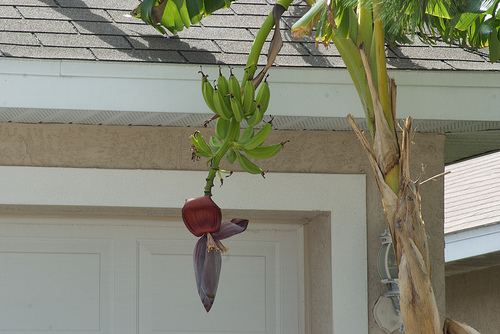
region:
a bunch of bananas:
[189, 71, 291, 171]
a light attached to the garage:
[372, 207, 434, 317]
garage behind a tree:
[0, 1, 499, 331]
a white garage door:
[0, 210, 305, 331]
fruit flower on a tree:
[179, 194, 249, 311]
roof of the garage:
[0, 0, 497, 70]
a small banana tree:
[139, 0, 498, 331]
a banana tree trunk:
[325, 19, 445, 330]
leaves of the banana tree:
[139, 3, 499, 60]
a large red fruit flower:
[180, 197, 250, 315]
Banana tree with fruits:
[135, 0, 499, 330]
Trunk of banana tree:
[344, 53, 473, 332]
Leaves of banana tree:
[132, 2, 499, 58]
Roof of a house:
[5, 0, 498, 69]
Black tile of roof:
[35, 29, 133, 49]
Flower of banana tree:
[176, 190, 250, 314]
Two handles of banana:
[176, 61, 287, 176]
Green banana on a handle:
[231, 150, 267, 181]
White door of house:
[5, 210, 303, 330]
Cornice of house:
[3, 61, 499, 127]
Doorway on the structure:
[5, 148, 385, 331]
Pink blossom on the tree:
[171, 192, 248, 311]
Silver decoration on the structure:
[371, 226, 411, 319]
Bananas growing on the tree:
[192, 61, 285, 175]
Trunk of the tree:
[353, 118, 444, 330]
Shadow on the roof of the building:
[46, 3, 220, 62]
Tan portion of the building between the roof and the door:
[5, 126, 172, 161]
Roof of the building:
[5, 3, 52, 51]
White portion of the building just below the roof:
[8, 66, 188, 103]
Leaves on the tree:
[339, 8, 492, 50]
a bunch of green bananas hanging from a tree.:
[195, 64, 286, 178]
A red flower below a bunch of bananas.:
[180, 192, 251, 313]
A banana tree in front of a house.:
[134, 0, 498, 332]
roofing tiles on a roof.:
[0, 2, 498, 70]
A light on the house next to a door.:
[365, 220, 409, 331]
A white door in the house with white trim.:
[2, 162, 367, 331]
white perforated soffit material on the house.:
[1, 106, 498, 167]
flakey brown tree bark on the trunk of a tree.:
[346, 43, 453, 332]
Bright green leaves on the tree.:
[133, 0, 498, 58]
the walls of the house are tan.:
[0, 120, 498, 331]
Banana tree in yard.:
[141, 3, 461, 328]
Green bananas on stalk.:
[185, 63, 288, 178]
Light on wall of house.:
[371, 226, 403, 332]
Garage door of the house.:
[9, 218, 310, 331]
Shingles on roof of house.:
[0, 2, 125, 58]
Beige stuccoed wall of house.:
[8, 128, 176, 163]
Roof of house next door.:
[449, 166, 493, 228]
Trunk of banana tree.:
[347, 85, 445, 332]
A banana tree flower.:
[174, 195, 258, 320]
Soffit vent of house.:
[11, 108, 164, 125]